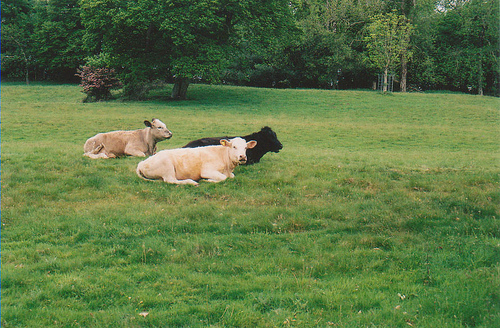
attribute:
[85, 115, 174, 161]
cow — tan, lying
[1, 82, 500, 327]
grass — low, green, field, lots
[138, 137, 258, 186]
cow — cream colored, looking, white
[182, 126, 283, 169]
cow — looking, black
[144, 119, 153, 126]
ear — pink inside, tagged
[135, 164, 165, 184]
tail — long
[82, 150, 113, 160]
tail — long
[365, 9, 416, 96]
tree — small, protected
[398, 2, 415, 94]
tree — big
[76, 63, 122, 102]
bush — purple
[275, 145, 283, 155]
mouth — open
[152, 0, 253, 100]
tree — green